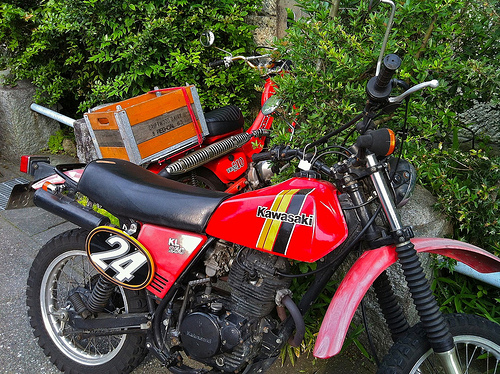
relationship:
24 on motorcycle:
[89, 235, 149, 282] [0, 55, 500, 374]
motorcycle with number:
[0, 55, 500, 374] [88, 232, 149, 282]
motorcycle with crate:
[0, 55, 500, 374] [80, 81, 214, 162]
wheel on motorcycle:
[21, 226, 146, 371] [0, 55, 500, 374]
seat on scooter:
[208, 104, 248, 136] [4, 45, 498, 372]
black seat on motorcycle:
[72, 146, 228, 238] [0, 55, 500, 374]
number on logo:
[88, 232, 149, 282] [81, 222, 158, 291]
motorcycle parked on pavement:
[61, 130, 478, 362] [3, 166, 343, 337]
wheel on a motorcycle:
[375, 311, 499, 371] [3, 0, 497, 370]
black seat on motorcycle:
[74, 155, 232, 238] [0, 55, 500, 374]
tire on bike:
[26, 228, 148, 372] [4, 2, 499, 372]